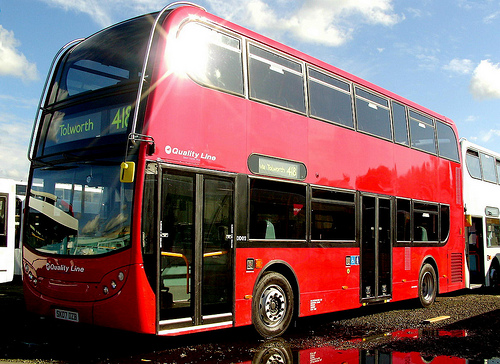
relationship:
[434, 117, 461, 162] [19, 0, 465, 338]
window on a bus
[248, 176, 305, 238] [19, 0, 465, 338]
window on a bus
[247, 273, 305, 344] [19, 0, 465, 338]
tire on bus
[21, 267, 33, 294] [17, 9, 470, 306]
headlight of bus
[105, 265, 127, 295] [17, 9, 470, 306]
headlight of bus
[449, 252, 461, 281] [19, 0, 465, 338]
vent on bus